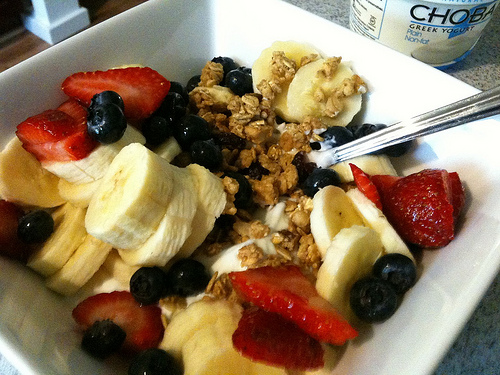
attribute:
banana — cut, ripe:
[312, 221, 383, 323]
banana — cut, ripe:
[306, 182, 370, 265]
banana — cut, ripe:
[0, 131, 72, 211]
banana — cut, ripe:
[78, 138, 181, 257]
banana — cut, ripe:
[24, 201, 93, 280]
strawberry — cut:
[67, 286, 167, 364]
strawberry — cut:
[225, 260, 360, 350]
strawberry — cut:
[226, 300, 327, 374]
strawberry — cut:
[56, 60, 174, 127]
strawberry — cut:
[346, 157, 389, 215]